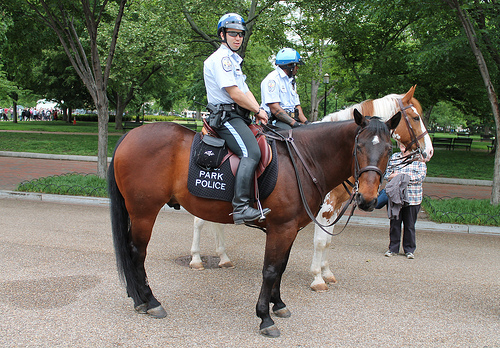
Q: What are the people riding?
A: Horses.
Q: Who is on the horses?
A: Police.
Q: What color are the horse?
A: Brown.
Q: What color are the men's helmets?
A: Blue.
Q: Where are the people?
A: In a park.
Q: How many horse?
A: Two.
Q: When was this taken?
A: During the day.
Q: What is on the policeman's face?
A: Sunglasses.